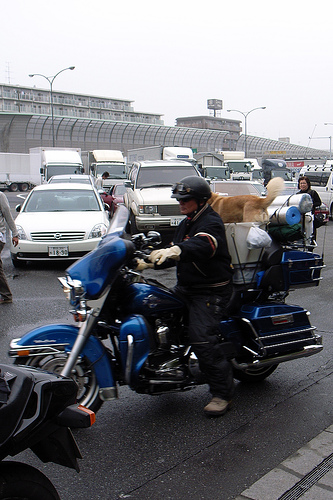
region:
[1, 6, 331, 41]
patch of clear gray skies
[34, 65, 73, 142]
street lamp for light at night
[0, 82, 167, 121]
building with balconies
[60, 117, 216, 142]
stadium wall type structure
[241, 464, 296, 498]
single brick for making ground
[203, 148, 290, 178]
row of tractor trailers parked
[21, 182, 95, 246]
parked automobile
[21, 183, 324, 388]
blue motorcycle with motorcyclist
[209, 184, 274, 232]
dog on back of motorcycle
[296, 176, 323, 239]
woman walking in background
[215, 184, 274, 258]
a dog standing on a bike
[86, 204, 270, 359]
a man driving a motorcycle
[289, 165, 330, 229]
a woman watching a man drive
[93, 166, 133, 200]
a person standing next to a car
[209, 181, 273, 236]
a dog standing behind a man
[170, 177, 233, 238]
a man wearing a helmet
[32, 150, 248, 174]
trucks parked in a parking lot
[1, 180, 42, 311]
a person walking passed parked cars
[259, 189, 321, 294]
items stapped on the back of a bike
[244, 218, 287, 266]
a bag hanging from a container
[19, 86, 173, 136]
a building standing behind a parking lot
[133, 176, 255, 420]
a man sitting on a motorcycle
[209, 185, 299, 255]
a dog standing on a motorcycle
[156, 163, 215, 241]
a man wearing a black helmet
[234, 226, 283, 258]
a bag hanging from a box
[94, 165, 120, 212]
a person entering a car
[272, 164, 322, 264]
a woman staring a man on a motorcycle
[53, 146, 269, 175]
truck parked in a parking lot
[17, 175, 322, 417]
a man is on a motorcycle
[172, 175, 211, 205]
the man is wearing a helmet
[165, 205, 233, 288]
the man is wearing a jacket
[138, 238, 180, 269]
the man is wearing gloves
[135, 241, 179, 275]
the gloves are light in color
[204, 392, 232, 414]
the man is wearing shoes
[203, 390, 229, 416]
the shoes are tan in color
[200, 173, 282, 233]
the dog is in the basket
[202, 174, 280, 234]
the dog is brown in color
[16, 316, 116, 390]
the fender is blue in color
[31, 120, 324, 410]
the motorcycle is blue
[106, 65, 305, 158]
the sky is overcast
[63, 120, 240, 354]
a busy parking lot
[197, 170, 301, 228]
this is a dog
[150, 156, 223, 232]
the helmet is black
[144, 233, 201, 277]
the gloves are tan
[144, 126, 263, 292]
the van is white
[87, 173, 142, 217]
a person getting in a car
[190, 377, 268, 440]
the shoes are tan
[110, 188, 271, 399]
man riding a motorcycle